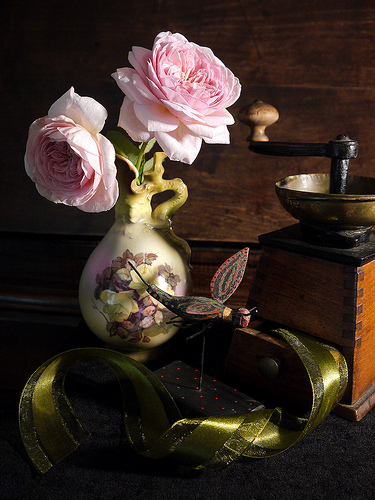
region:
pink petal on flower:
[157, 123, 203, 168]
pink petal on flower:
[128, 96, 181, 135]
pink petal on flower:
[115, 96, 149, 146]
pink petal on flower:
[186, 122, 214, 137]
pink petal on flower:
[201, 122, 233, 146]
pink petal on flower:
[73, 93, 106, 134]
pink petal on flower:
[95, 131, 119, 189]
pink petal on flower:
[74, 177, 120, 213]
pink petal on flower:
[91, 130, 119, 191]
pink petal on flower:
[70, 93, 106, 139]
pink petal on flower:
[42, 87, 77, 118]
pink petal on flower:
[153, 129, 198, 165]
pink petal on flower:
[169, 108, 212, 139]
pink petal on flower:
[128, 70, 153, 101]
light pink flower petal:
[118, 98, 151, 144]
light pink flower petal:
[132, 98, 180, 139]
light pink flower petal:
[153, 126, 202, 170]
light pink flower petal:
[110, 64, 140, 107]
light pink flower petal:
[124, 43, 147, 74]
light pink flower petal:
[193, 108, 234, 128]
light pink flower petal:
[73, 92, 111, 134]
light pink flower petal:
[45, 85, 75, 115]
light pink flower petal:
[96, 133, 117, 190]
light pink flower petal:
[70, 177, 121, 215]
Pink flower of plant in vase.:
[24, 85, 119, 214]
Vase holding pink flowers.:
[75, 145, 194, 353]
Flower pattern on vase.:
[93, 249, 183, 342]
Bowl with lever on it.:
[275, 171, 373, 225]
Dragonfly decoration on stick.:
[128, 245, 254, 340]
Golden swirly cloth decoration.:
[19, 329, 349, 473]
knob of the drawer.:
[256, 355, 282, 379]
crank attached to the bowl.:
[237, 98, 355, 197]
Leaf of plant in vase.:
[104, 127, 143, 185]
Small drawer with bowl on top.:
[223, 219, 373, 417]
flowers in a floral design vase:
[32, 33, 233, 352]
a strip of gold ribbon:
[17, 325, 345, 460]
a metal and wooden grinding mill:
[229, 96, 373, 417]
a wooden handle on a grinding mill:
[241, 95, 275, 147]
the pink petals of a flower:
[19, 89, 113, 214]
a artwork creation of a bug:
[135, 243, 255, 339]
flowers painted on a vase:
[93, 244, 181, 339]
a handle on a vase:
[141, 171, 192, 247]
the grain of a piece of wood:
[207, 167, 261, 232]